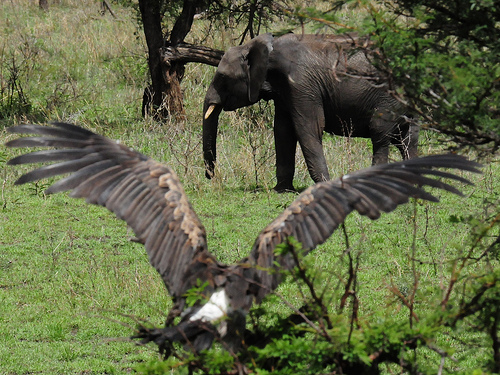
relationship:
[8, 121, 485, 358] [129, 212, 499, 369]
bird in tree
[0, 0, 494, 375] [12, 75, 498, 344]
weeds on ground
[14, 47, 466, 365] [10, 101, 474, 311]
bird spread out wings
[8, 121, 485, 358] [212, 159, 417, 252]
bird has wing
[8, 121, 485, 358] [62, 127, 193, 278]
bird has wing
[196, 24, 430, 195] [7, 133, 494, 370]
elephant in grass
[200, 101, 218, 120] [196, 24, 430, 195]
tusks on elephant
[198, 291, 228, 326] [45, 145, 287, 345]
white feather on bird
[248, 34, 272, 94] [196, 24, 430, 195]
ear on elephant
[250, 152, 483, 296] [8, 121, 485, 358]
wing on bird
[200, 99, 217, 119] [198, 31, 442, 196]
tusks on elephant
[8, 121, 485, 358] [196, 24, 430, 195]
bird behind elephant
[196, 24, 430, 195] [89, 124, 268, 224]
elephant look food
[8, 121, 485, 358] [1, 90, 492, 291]
bird has wingspan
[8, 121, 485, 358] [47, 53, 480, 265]
bird in field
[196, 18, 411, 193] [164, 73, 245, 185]
elephant has trunk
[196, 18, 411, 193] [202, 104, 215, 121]
elephant has tusk